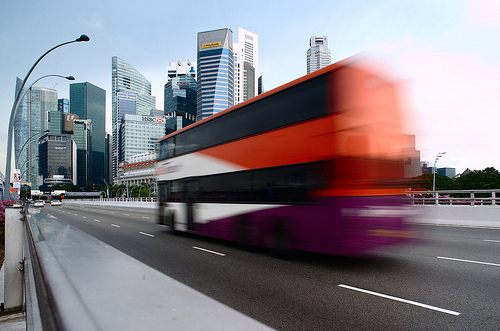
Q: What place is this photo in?
A: It is at the city.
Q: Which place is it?
A: It is a city.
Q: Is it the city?
A: Yes, it is the city.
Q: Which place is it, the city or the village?
A: It is the city.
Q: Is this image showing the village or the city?
A: It is showing the city.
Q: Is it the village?
A: No, it is the city.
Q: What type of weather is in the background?
A: It is clear.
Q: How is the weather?
A: It is clear.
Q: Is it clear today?
A: Yes, it is clear.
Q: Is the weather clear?
A: Yes, it is clear.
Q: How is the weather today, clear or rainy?
A: It is clear.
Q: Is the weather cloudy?
A: No, it is clear.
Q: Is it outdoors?
A: Yes, it is outdoors.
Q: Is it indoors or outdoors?
A: It is outdoors.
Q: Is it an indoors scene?
A: No, it is outdoors.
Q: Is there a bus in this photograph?
A: Yes, there is a bus.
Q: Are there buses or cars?
A: Yes, there is a bus.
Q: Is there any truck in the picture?
A: No, there are no trucks.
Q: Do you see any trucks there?
A: No, there are no trucks.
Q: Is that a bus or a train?
A: That is a bus.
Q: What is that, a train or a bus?
A: That is a bus.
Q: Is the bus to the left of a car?
A: No, the bus is to the right of a car.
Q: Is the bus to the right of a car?
A: Yes, the bus is to the right of a car.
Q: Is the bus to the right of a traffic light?
A: No, the bus is to the right of a car.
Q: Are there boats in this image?
A: No, there are no boats.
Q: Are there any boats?
A: No, there are no boats.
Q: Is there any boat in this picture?
A: No, there are no boats.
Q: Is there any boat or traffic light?
A: No, there are no boats or traffic lights.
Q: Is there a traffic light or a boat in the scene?
A: No, there are no boats or traffic lights.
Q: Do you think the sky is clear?
A: Yes, the sky is clear.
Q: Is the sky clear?
A: Yes, the sky is clear.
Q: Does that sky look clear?
A: Yes, the sky is clear.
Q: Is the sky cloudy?
A: No, the sky is clear.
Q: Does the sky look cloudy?
A: No, the sky is clear.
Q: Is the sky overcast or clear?
A: The sky is clear.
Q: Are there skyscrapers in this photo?
A: Yes, there are skyscrapers.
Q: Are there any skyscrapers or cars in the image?
A: Yes, there are skyscrapers.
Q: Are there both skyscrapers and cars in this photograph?
A: Yes, there are both skyscrapers and cars.